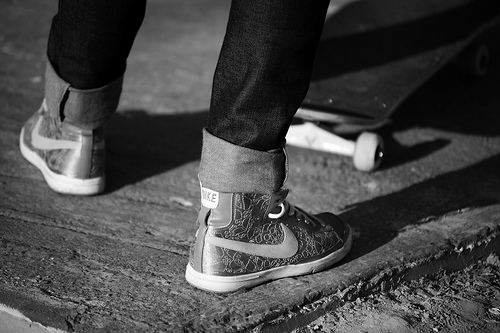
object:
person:
[20, 1, 355, 292]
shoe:
[18, 98, 108, 196]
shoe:
[182, 183, 353, 293]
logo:
[30, 114, 80, 153]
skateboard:
[283, 1, 498, 173]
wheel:
[353, 131, 384, 174]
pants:
[44, 1, 330, 194]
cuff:
[44, 62, 125, 126]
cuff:
[200, 126, 287, 195]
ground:
[1, 0, 499, 333]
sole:
[19, 127, 104, 194]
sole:
[184, 224, 353, 291]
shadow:
[87, 2, 498, 275]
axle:
[284, 120, 387, 173]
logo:
[210, 221, 300, 259]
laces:
[266, 200, 326, 230]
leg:
[42, 0, 148, 126]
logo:
[199, 187, 220, 209]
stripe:
[76, 129, 96, 179]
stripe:
[190, 205, 209, 271]